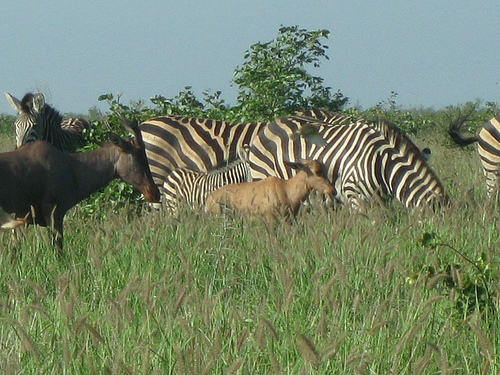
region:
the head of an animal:
[115, 136, 159, 206]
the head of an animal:
[293, 158, 337, 198]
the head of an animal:
[10, 99, 47, 152]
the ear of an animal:
[105, 131, 130, 152]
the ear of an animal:
[290, 160, 312, 175]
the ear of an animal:
[236, 146, 248, 163]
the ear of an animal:
[5, 91, 19, 113]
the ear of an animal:
[33, 93, 45, 111]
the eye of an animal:
[314, 169, 323, 179]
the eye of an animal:
[30, 120, 38, 130]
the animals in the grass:
[12, 64, 483, 236]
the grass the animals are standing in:
[29, 130, 486, 362]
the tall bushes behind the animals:
[104, 43, 329, 230]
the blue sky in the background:
[10, 2, 489, 117]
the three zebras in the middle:
[141, 103, 423, 214]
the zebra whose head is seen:
[14, 82, 71, 159]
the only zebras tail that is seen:
[442, 108, 497, 176]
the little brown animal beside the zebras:
[193, 148, 340, 227]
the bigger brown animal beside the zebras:
[17, 119, 159, 234]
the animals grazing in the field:
[25, 75, 494, 251]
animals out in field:
[23, 35, 446, 287]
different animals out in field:
[6, 60, 466, 300]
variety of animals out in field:
[7, 71, 424, 286]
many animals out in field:
[5, 56, 450, 311]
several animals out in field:
[4, 56, 461, 267]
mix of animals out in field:
[8, 47, 460, 321]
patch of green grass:
[96, 250, 399, 338]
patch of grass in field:
[78, 250, 397, 350]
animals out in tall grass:
[14, 38, 456, 347]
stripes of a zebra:
[312, 132, 385, 170]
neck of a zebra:
[383, 128, 467, 218]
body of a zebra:
[240, 111, 384, 172]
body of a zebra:
[134, 110, 234, 181]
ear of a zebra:
[3, 82, 30, 109]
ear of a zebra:
[29, 82, 54, 118]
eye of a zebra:
[25, 113, 51, 130]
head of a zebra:
[3, 114, 52, 147]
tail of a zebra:
[443, 102, 483, 145]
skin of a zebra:
[155, 124, 220, 159]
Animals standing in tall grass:
[5, 35, 455, 312]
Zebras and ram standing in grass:
[1, 35, 436, 302]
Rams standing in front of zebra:
[0, 31, 445, 267]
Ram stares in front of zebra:
[0, 40, 165, 275]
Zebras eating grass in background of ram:
[1, 40, 448, 306]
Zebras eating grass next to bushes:
[1, 21, 446, 281]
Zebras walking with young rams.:
[1, 35, 446, 305]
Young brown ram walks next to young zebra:
[1, 42, 447, 322]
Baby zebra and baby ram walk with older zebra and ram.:
[3, 41, 446, 291]